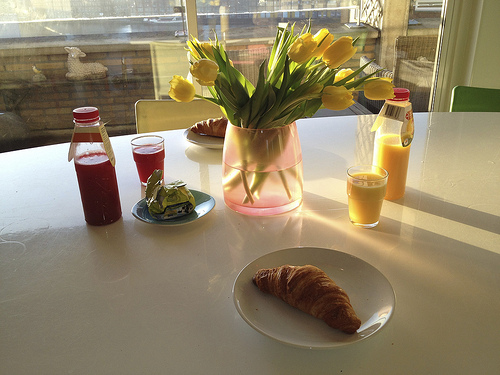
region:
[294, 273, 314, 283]
croissant on the plate.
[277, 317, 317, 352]
plate on the table.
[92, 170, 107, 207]
red juice in bottle.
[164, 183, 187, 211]
wrapper on the plate.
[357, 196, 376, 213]
orange juice in the glass.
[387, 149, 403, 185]
orange juice in the bottle.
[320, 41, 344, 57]
yellow flower on the stem.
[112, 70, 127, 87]
wall made of brick.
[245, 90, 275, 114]
stems in the vase.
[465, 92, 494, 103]
chair near the table.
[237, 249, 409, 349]
a croissant on a white plate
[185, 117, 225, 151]
a croissant on a white plate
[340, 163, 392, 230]
orange juice in a glass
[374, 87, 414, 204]
orange juice in a bottle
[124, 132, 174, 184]
red juice in a glass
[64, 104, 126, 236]
red juice in a bottle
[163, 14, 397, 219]
yellow roses in a vase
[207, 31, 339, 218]
flowers in a vase sitting on a table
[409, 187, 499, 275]
shadows on a table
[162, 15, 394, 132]
a bunch of yellow roses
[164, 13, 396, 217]
yellow tulips in a vase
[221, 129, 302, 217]
stems of tulips in a vase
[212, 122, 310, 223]
pink vase over a table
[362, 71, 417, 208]
a bottle of orange juice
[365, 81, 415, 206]
bottle has a red cap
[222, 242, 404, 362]
a white dish with a croissant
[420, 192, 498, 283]
shadows on the table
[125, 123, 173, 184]
a glass with juice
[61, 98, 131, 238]
a bottle with juice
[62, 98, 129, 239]
red cap of juice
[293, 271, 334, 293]
croissant on the plate.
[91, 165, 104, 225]
red juice in the bottle.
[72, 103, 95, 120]
top on the bottle.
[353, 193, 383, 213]
orange juice in cup.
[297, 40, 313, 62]
yellow flower on stem.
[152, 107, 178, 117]
chair near the table.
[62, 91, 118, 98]
wall made of brick.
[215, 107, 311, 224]
A pink vase on the table.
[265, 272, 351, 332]
Croissant on the white plate.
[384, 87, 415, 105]
The bottle cap is red.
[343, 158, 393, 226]
A glass of orange juice on table.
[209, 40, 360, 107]
Yellow flowers in the vase.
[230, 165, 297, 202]
Water in the bottom of vase.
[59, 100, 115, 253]
juice in the bottle.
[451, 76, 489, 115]
A green chair at the table.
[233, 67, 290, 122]
Green stems on the flower.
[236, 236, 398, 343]
the plate is round and white.